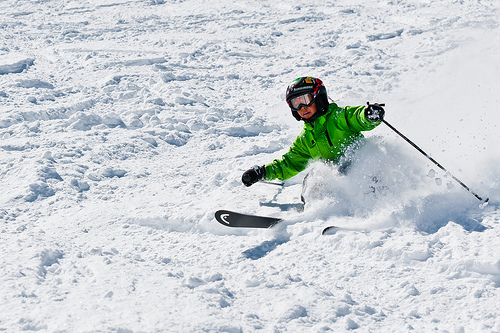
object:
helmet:
[284, 76, 328, 123]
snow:
[48, 53, 148, 130]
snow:
[95, 231, 487, 331]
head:
[287, 78, 325, 119]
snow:
[30, 44, 201, 181]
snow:
[0, 2, 498, 327]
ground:
[0, 243, 500, 333]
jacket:
[262, 102, 383, 181]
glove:
[242, 165, 266, 187]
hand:
[241, 166, 261, 187]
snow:
[58, 258, 465, 320]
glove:
[363, 101, 385, 122]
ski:
[214, 209, 284, 228]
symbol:
[220, 213, 230, 224]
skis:
[214, 209, 369, 234]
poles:
[378, 118, 490, 203]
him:
[241, 76, 386, 206]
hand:
[365, 104, 386, 123]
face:
[291, 93, 318, 119]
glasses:
[286, 87, 321, 111]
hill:
[0, 1, 499, 333]